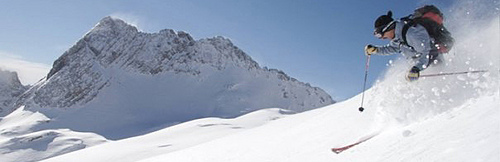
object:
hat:
[374, 10, 397, 33]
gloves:
[405, 66, 421, 81]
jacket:
[376, 20, 439, 71]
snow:
[39, 0, 500, 162]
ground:
[423, 107, 489, 135]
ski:
[332, 133, 381, 155]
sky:
[286, 14, 327, 66]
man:
[365, 5, 457, 82]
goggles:
[374, 20, 396, 38]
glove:
[364, 44, 377, 55]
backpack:
[400, 4, 455, 63]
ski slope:
[0, 0, 500, 162]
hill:
[0, 15, 338, 162]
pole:
[357, 50, 371, 113]